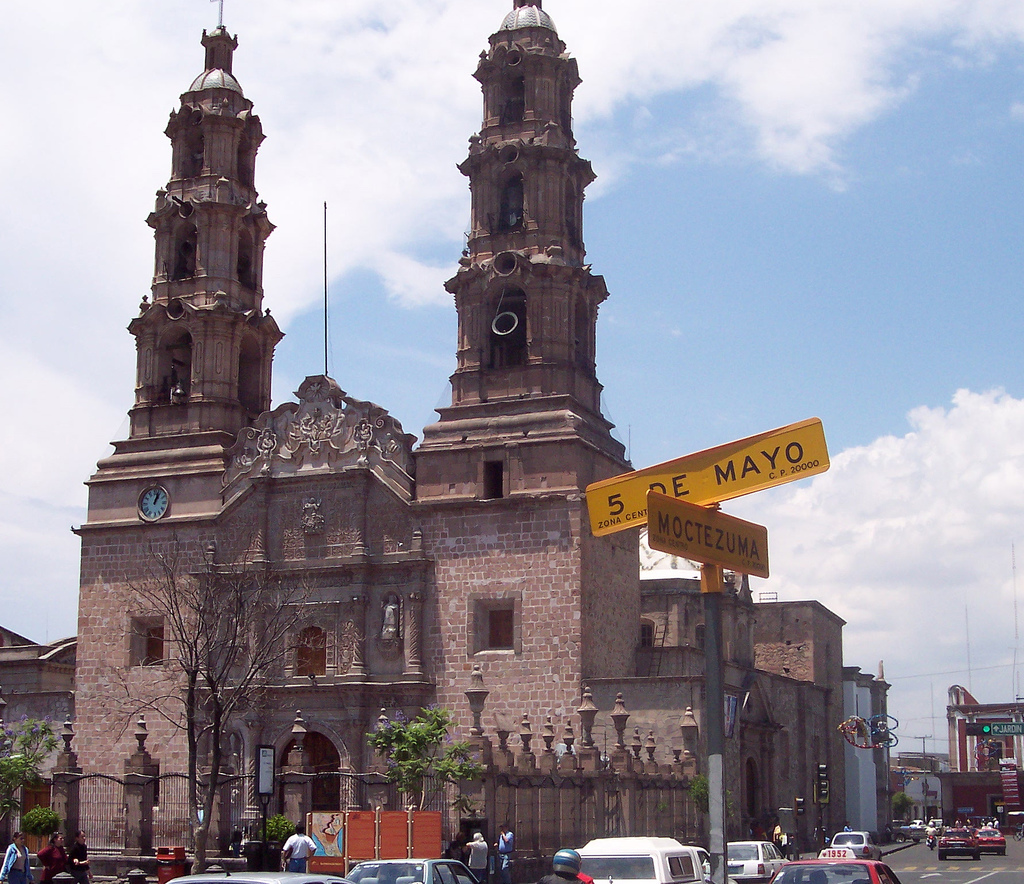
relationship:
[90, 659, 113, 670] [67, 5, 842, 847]
brick in building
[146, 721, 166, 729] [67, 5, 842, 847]
brick in building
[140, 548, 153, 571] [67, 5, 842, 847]
brick in building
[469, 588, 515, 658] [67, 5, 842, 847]
window in building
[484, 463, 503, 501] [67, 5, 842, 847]
window on building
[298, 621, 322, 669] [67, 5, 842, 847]
window on building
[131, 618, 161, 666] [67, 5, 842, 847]
window on building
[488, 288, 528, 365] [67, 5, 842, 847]
window on building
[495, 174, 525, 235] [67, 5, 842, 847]
window on building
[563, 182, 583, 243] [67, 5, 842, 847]
window on building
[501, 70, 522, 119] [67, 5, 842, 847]
window on building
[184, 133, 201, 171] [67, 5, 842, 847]
window on building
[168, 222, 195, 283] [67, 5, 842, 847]
window on building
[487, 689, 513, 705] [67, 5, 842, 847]
brick in building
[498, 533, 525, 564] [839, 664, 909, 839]
brick in building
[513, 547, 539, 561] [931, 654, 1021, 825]
brick in building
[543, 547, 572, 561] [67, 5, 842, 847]
brick in building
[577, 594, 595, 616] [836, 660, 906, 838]
brick in building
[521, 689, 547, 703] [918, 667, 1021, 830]
brick in building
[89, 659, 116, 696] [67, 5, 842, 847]
brick in building